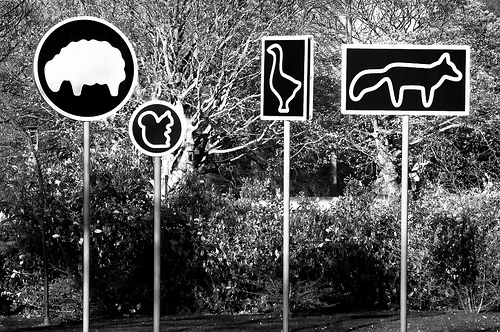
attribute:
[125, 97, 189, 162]
sign — round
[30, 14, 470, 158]
signs — black and white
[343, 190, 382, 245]
ground — black and white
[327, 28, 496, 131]
sign — square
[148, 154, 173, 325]
pole — black and white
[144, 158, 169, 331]
pole — gray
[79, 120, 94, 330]
pole — grey, metal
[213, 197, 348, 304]
bush — black and white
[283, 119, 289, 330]
pole — metal, white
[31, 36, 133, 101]
sheep — white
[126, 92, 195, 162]
sign — black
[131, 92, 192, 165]
sign — round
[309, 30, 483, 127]
sign — black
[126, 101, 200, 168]
squirrel — black and white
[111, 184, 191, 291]
pole — holding up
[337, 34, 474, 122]
sign — animal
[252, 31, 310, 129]
sign — animal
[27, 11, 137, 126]
sign — animal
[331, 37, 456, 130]
symbol — sheep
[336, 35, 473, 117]
fox — picture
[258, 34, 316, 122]
sign — black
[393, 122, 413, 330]
pole — black and white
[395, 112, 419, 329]
pole — holding up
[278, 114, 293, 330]
pole — holding up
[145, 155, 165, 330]
pole — holding up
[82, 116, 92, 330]
pole — holding up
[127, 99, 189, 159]
sign — animal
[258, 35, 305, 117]
duck — black and white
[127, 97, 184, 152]
picture — squirrel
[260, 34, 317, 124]
duck sign — black and white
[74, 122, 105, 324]
pole — standing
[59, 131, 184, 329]
pole — gray